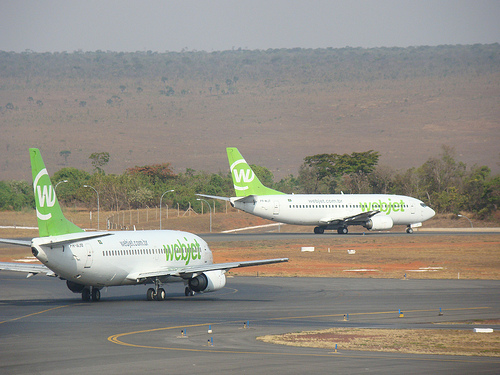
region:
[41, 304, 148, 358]
this is the runway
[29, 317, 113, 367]
the runway is clean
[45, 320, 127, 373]
the runway is made of tarmac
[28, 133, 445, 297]
these are two airplanes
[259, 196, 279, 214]
the airplane is white in color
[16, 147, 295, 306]
the airplane is big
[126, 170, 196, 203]
these are several trees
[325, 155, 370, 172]
the leaves are green in color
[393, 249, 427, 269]
the ground is sandy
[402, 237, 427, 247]
the sand is brown in color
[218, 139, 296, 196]
tail wing on a jetliner.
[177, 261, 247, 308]
jet engine on wing.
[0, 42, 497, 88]
a large green forest.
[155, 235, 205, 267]
a company name.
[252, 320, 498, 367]
a patch of dry grass.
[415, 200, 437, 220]
a cock pit on a jet.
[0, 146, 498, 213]
a field of green plants.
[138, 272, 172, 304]
landing gear.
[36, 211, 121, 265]
right tail wing.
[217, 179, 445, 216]
large fuselage on an airport runway.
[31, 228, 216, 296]
the plane's body is white in color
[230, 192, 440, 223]
the plane's body is white in color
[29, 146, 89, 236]
the tail is green and white in color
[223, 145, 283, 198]
the tail is green and white in color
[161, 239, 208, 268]
the plane has lettering on the side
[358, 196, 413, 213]
the plane has lettering on the side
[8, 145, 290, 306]
the plane is on the pavement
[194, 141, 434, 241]
the plane is facing right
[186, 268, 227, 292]
the engine is under the wing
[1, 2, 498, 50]
the sky is grey in color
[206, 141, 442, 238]
The plane is green and white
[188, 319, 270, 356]
Blue markers on the tarmac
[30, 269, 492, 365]
There are yellow lines on the tarmac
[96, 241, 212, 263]
The plane has small windows on its side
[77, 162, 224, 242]
The light poles are white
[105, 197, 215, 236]
Grey chain link fence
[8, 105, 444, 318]
There are two planes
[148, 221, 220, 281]
The side of the plane says webjet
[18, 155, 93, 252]
The tail is green with white writing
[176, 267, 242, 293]
The engine is black and white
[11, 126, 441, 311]
Two green and white jets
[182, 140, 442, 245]
First green and white jet preparing for takeoff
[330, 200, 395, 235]
Right wing of first green and white jet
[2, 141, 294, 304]
Second green and white jet preparing for takeoff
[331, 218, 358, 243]
Right wheel of first green and white jet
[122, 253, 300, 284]
Right wing of second green and white jet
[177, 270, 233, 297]
Second jet's right engine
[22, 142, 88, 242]
Stabilizer of second jet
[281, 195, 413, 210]
Passenger windows of first green and white jet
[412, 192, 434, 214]
Cockpit windshield of first green and white jet